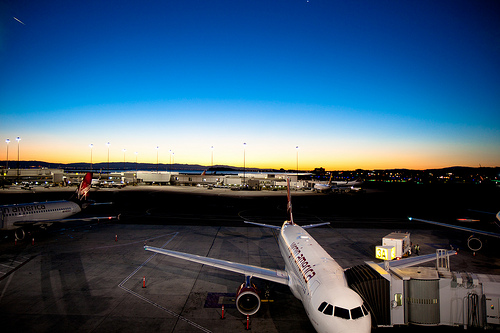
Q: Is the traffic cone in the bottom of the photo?
A: Yes, the traffic cone is in the bottom of the image.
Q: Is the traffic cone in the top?
A: No, the traffic cone is in the bottom of the image.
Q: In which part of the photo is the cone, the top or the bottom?
A: The cone is in the bottom of the image.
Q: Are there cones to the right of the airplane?
A: No, the cone is to the left of the airplane.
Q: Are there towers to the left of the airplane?
A: No, there is a cone to the left of the airplane.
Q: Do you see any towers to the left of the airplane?
A: No, there is a cone to the left of the airplane.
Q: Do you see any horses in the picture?
A: No, there are no horses.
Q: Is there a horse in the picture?
A: No, there are no horses.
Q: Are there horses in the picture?
A: No, there are no horses.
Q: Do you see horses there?
A: No, there are no horses.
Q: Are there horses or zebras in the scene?
A: No, there are no horses or zebras.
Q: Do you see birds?
A: No, there are no birds.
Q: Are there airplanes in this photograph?
A: Yes, there is an airplane.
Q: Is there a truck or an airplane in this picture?
A: Yes, there is an airplane.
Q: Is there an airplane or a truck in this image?
A: Yes, there is an airplane.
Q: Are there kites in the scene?
A: No, there are no kites.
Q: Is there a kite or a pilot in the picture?
A: No, there are no kites or pilots.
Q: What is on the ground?
A: The airplane is on the ground.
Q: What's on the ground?
A: The airplane is on the ground.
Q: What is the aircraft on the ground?
A: The aircraft is an airplane.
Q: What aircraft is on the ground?
A: The aircraft is an airplane.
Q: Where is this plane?
A: The plane is on the ground.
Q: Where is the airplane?
A: The plane is on the ground.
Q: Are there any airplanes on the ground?
A: Yes, there is an airplane on the ground.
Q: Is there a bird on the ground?
A: No, there is an airplane on the ground.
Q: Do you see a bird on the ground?
A: No, there is an airplane on the ground.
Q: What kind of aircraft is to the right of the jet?
A: The aircraft is an airplane.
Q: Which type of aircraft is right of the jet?
A: The aircraft is an airplane.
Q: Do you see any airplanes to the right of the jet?
A: Yes, there is an airplane to the right of the jet.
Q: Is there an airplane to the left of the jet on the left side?
A: No, the airplane is to the right of the jet.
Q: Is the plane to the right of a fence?
A: No, the plane is to the right of the jet.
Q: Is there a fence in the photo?
A: No, there are no fences.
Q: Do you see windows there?
A: Yes, there are windows.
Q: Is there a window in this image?
A: Yes, there are windows.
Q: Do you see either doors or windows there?
A: Yes, there are windows.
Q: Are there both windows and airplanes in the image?
A: Yes, there are both windows and an airplane.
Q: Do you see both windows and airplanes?
A: Yes, there are both windows and an airplane.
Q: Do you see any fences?
A: No, there are no fences.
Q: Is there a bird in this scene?
A: No, there are no birds.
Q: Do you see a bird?
A: No, there are no birds.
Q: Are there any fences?
A: No, there are no fences.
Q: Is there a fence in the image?
A: No, there are no fences.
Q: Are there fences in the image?
A: No, there are no fences.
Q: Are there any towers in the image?
A: No, there are no towers.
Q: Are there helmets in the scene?
A: No, there are no helmets.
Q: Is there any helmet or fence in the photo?
A: No, there are no helmets or fences.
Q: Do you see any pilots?
A: No, there are no pilots.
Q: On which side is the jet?
A: The jet is on the left of the image.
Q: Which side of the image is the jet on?
A: The jet is on the left of the image.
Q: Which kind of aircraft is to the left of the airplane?
A: The aircraft is a jet.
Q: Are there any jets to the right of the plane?
A: No, the jet is to the left of the plane.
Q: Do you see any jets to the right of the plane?
A: No, the jet is to the left of the plane.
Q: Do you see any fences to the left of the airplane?
A: No, there is a jet to the left of the airplane.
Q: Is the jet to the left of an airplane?
A: Yes, the jet is to the left of an airplane.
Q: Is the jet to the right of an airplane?
A: No, the jet is to the left of an airplane.